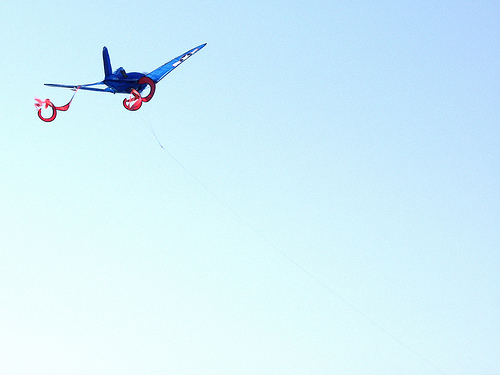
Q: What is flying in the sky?
A: Airplane.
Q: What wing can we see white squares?
A: Right.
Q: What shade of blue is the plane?
A: Royal.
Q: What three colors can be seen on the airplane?
A: Red, white, blue.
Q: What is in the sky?
A: The plane.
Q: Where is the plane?
A: The sky.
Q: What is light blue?
A: The sky.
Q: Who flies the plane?
A: A pilot.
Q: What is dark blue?
A: The airplane.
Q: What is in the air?
A: A kite.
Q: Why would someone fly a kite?
A: For fun.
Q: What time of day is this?
A: Daylight.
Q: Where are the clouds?
A: Nowhere.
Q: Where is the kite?
A: In the sky.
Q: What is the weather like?
A: Sunny.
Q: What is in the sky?
A: A kite.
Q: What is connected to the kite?
A: A string.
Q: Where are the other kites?
A: Nowhere.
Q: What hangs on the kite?
A: Decorations.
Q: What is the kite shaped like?
A: Airplane.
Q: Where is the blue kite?
A: In the air.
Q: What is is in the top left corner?
A: A kite.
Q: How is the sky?
A: Clear.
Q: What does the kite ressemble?
A: A plane.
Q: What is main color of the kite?
A: Blue.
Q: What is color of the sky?
A: Blue.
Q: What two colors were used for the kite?
A: Red and blue.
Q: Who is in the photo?
A: No one.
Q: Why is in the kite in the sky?
A: Being flown.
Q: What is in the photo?
A: Kite.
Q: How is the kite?
A: In motion.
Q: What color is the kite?
A: Blue.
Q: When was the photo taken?
A: Daytime.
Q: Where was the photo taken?
A: In the skies above Cleveland.